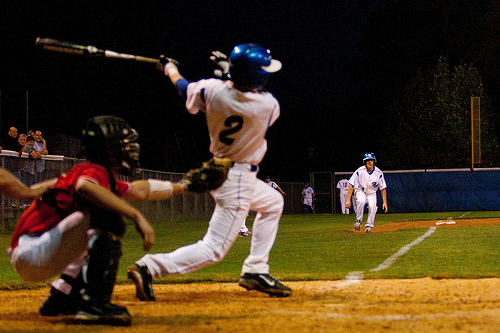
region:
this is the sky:
[308, 23, 350, 79]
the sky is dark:
[317, 29, 354, 65]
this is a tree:
[393, 56, 482, 163]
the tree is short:
[403, 51, 498, 146]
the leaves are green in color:
[430, 86, 456, 113]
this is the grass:
[346, 238, 407, 273]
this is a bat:
[30, 25, 165, 77]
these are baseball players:
[52, 3, 397, 274]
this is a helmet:
[229, 41, 284, 86]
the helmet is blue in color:
[251, 58, 258, 66]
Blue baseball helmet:
[227, 43, 281, 86]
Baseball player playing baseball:
[347, 150, 388, 228]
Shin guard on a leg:
[84, 232, 118, 301]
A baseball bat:
[35, 35, 178, 65]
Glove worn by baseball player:
[156, 54, 178, 67]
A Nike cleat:
[236, 270, 292, 295]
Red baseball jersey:
[13, 163, 128, 240]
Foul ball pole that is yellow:
[470, 95, 476, 165]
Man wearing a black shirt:
[0, 125, 15, 145]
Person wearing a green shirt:
[20, 131, 35, 156]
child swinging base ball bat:
[122, 34, 305, 324]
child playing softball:
[123, 38, 301, 313]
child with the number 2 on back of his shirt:
[123, 39, 303, 316]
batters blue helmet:
[221, 40, 284, 77]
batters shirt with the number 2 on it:
[181, 76, 283, 165]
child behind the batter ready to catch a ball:
[6, 110, 241, 325]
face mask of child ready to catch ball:
[78, 107, 148, 180]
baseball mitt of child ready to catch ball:
[178, 154, 233, 198]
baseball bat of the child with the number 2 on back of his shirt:
[29, 29, 174, 73]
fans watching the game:
[5, 117, 50, 183]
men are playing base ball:
[10, 18, 498, 331]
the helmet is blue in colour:
[218, 26, 283, 90]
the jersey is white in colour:
[172, 73, 277, 145]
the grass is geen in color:
[331, 229, 466, 271]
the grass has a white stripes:
[334, 230, 482, 260]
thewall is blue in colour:
[412, 176, 478, 208]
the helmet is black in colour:
[62, 102, 149, 174]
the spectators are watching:
[1, 117, 50, 174]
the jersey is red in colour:
[67, 168, 108, 210]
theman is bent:
[341, 114, 394, 250]